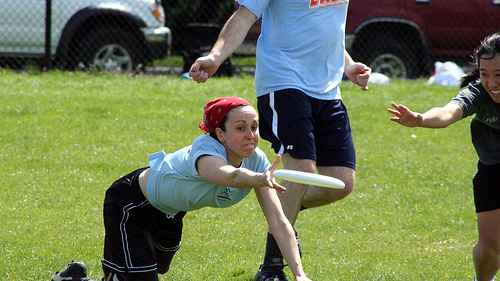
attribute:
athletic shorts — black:
[256, 92, 360, 174]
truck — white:
[4, 4, 169, 74]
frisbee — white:
[274, 165, 353, 191]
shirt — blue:
[233, 0, 350, 97]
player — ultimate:
[183, 0, 375, 277]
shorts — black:
[80, 157, 192, 278]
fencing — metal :
[0, 3, 495, 65]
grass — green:
[4, 57, 498, 278]